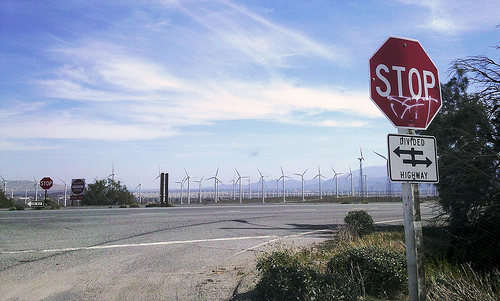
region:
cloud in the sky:
[173, 77, 286, 129]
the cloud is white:
[147, 74, 255, 133]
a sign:
[390, 138, 437, 183]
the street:
[125, 208, 170, 225]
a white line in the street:
[111, 237, 162, 252]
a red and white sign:
[70, 177, 85, 194]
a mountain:
[13, 176, 28, 191]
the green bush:
[457, 146, 490, 213]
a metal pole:
[400, 199, 422, 289]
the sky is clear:
[241, 138, 303, 165]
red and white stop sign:
[370, 28, 438, 128]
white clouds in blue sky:
[47, 32, 116, 117]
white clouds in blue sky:
[207, 76, 268, 152]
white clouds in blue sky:
[140, 65, 205, 118]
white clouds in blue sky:
[253, 62, 295, 114]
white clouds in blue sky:
[183, 57, 236, 123]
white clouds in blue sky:
[267, 92, 322, 165]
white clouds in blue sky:
[164, 28, 221, 88]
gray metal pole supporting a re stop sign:
[401, 125, 421, 300]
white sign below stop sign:
[387, 133, 439, 181]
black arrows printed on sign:
[393, 146, 434, 166]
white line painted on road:
[3, 234, 273, 253]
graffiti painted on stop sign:
[386, 92, 437, 127]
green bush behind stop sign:
[423, 73, 499, 267]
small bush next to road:
[344, 210, 374, 232]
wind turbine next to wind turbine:
[296, 167, 310, 199]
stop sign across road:
[38, 175, 55, 207]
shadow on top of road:
[219, 215, 345, 235]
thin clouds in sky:
[3, 2, 497, 179]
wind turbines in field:
[8, 166, 368, 198]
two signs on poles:
[38, 176, 85, 204]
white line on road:
[15, 225, 325, 252]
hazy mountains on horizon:
[171, 163, 389, 193]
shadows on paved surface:
[221, 220, 328, 243]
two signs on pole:
[368, 34, 440, 298]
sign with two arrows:
[389, 132, 438, 182]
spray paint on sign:
[388, 90, 438, 121]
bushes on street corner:
[273, 210, 458, 299]